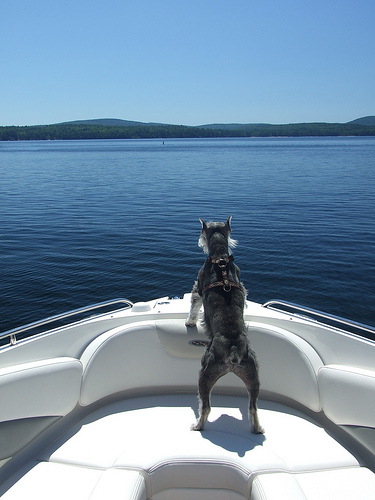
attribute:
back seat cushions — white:
[1, 316, 374, 434]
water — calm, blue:
[1, 136, 373, 327]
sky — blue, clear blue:
[0, 2, 374, 113]